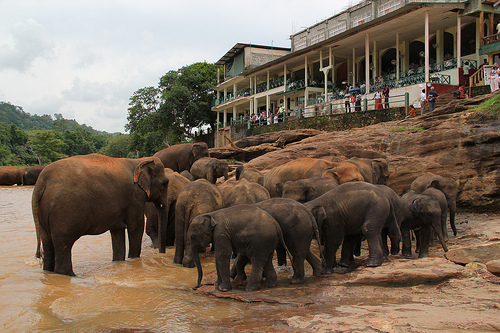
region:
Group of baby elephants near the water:
[173, 171, 463, 293]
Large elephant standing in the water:
[32, 155, 169, 277]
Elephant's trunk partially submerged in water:
[158, 210, 168, 257]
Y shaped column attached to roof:
[318, 50, 333, 102]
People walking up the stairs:
[418, 85, 437, 115]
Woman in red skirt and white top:
[373, 85, 383, 109]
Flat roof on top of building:
[211, 41, 289, 76]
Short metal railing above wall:
[216, 92, 411, 141]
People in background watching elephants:
[234, 102, 291, 124]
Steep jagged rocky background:
[209, 93, 498, 207]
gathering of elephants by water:
[31, 141, 457, 292]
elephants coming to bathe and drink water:
[29, 140, 459, 290]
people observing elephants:
[253, 85, 391, 113]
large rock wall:
[211, 127, 498, 196]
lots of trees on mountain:
[2, 98, 176, 171]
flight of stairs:
[428, 60, 496, 113]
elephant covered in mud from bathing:
[50, 150, 154, 203]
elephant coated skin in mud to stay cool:
[269, 154, 362, 190]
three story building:
[213, 38, 497, 122]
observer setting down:
[403, 103, 417, 118]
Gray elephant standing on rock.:
[183, 213, 280, 276]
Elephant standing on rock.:
[279, 200, 325, 294]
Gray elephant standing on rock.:
[313, 194, 386, 266]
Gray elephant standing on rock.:
[406, 193, 441, 260]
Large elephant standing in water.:
[46, 156, 143, 238]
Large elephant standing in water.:
[178, 181, 206, 221]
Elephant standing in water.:
[196, 152, 223, 179]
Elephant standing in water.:
[166, 140, 197, 167]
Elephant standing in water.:
[278, 148, 368, 195]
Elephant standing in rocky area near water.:
[236, 163, 260, 190]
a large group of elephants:
[33, 138, 461, 300]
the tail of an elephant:
[29, 217, 44, 261]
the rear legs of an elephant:
[30, 234, 80, 282]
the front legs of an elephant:
[106, 218, 143, 264]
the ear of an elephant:
[126, 162, 151, 194]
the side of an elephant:
[56, 168, 123, 215]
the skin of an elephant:
[60, 168, 123, 215]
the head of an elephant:
[130, 158, 174, 215]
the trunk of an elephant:
[154, 193, 171, 255]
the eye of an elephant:
[159, 174, 169, 189]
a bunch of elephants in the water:
[26, 142, 455, 284]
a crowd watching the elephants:
[233, 80, 394, 125]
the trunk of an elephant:
[188, 245, 205, 289]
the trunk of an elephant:
[447, 190, 463, 239]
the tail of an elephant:
[30, 194, 49, 262]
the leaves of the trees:
[14, 115, 36, 139]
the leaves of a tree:
[165, 80, 207, 114]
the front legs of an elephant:
[208, 230, 238, 293]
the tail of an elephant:
[313, 213, 329, 273]